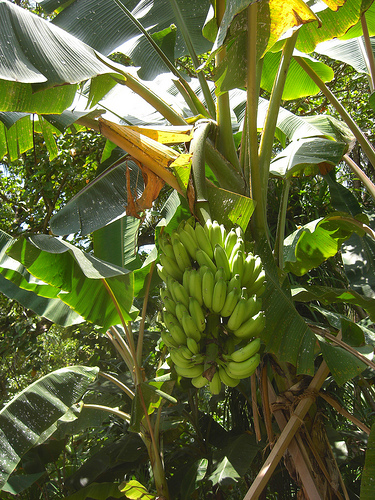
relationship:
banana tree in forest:
[55, 22, 334, 457] [122, 194, 307, 382]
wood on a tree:
[244, 355, 336, 485] [25, 15, 344, 325]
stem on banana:
[200, 324, 217, 408] [151, 218, 265, 391]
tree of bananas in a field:
[4, 6, 364, 497] [86, 390, 294, 490]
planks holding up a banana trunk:
[225, 369, 338, 478] [246, 363, 361, 496]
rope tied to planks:
[268, 384, 348, 498] [227, 320, 349, 494]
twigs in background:
[11, 178, 74, 250] [81, 427, 241, 500]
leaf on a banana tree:
[211, 0, 268, 94] [2, 1, 372, 498]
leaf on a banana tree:
[87, 113, 209, 213] [2, 1, 372, 498]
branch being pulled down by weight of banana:
[171, 110, 214, 219] [151, 218, 265, 391]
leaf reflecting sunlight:
[1, 0, 190, 126] [70, 65, 188, 126]